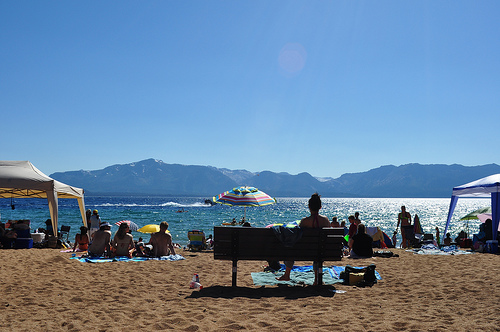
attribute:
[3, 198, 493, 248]
water — large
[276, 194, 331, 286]
woman — relaxing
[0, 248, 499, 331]
beach — sandy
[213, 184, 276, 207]
beach umbrella — striped, blue,pink,white, multicolored, large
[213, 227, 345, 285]
bench — wood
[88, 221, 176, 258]
people — relaxing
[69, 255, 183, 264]
towel — blue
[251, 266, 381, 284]
towel — blue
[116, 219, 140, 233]
umbrella — american flag design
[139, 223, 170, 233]
umbrella — yellow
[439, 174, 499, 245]
canopy — large, blue, white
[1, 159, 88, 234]
canopy — large, tan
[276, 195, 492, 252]
sun — a reflection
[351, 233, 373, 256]
shirt — black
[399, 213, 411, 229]
bikini — green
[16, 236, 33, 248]
ice chest — blue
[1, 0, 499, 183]
sky — cloudless, clear, bright blue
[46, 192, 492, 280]
people — lounging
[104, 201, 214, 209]
wave — white